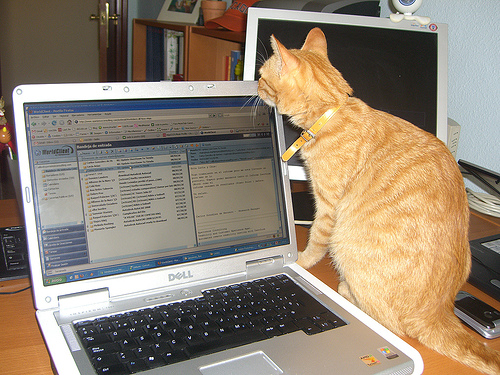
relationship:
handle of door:
[91, 10, 120, 54] [90, 4, 117, 85]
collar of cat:
[276, 103, 333, 161] [243, 45, 450, 307]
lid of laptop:
[10, 81, 297, 270] [36, 95, 402, 375]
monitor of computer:
[233, 13, 439, 184] [235, 13, 436, 191]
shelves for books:
[135, 19, 258, 88] [146, 38, 177, 71]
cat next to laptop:
[243, 45, 450, 307] [36, 95, 402, 375]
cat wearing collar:
[243, 45, 450, 307] [276, 103, 333, 161]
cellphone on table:
[450, 281, 498, 335] [8, 183, 498, 352]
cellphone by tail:
[450, 281, 498, 335] [419, 323, 495, 361]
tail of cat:
[419, 323, 495, 361] [243, 45, 450, 307]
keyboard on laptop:
[84, 266, 300, 373] [36, 95, 402, 375]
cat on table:
[243, 45, 450, 307] [8, 183, 498, 352]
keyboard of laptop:
[84, 266, 300, 373] [36, 95, 402, 375]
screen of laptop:
[34, 90, 265, 245] [36, 95, 402, 375]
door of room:
[90, 4, 117, 85] [1, 1, 499, 350]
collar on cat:
[276, 103, 333, 161] [243, 45, 450, 307]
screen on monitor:
[34, 90, 265, 245] [233, 13, 439, 184]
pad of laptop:
[207, 349, 272, 373] [36, 95, 402, 375]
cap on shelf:
[212, 3, 265, 32] [140, 11, 272, 87]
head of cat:
[253, 37, 335, 114] [243, 45, 450, 307]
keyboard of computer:
[84, 266, 300, 373] [235, 13, 436, 191]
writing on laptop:
[169, 265, 191, 289] [36, 95, 402, 375]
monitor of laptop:
[23, 92, 274, 264] [36, 95, 402, 375]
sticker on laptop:
[362, 356, 374, 371] [36, 95, 402, 375]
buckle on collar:
[303, 130, 316, 142] [276, 103, 333, 161]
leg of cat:
[307, 196, 361, 287] [243, 45, 450, 307]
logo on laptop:
[380, 338, 396, 359] [36, 95, 402, 375]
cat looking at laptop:
[243, 45, 450, 307] [36, 95, 402, 375]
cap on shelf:
[204, 0, 264, 32] [140, 11, 272, 87]